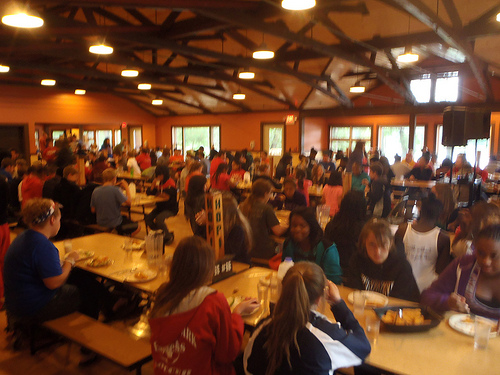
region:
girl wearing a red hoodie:
[142, 228, 249, 373]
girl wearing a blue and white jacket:
[227, 266, 383, 373]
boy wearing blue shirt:
[0, 195, 117, 332]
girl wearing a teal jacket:
[273, 205, 347, 291]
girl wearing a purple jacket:
[406, 223, 498, 316]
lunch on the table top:
[370, 298, 446, 336]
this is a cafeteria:
[2, 112, 494, 373]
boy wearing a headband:
[0, 188, 90, 328]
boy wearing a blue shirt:
[84, 166, 135, 236]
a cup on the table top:
[461, 310, 493, 355]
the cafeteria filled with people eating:
[0, 129, 495, 373]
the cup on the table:
[365, 314, 379, 347]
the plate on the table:
[348, 288, 387, 308]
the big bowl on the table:
[374, 304, 440, 331]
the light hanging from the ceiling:
[249, 34, 274, 61]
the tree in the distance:
[1, 13, 46, 28]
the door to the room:
[260, 120, 285, 169]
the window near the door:
[172, 124, 220, 159]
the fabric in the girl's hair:
[25, 198, 54, 225]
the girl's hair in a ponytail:
[263, 259, 325, 374]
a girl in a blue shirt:
[6, 197, 91, 322]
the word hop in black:
[211, 197, 226, 238]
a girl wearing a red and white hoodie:
[151, 232, 243, 374]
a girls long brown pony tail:
[266, 271, 310, 370]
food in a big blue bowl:
[369, 300, 440, 331]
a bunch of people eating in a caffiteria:
[3, 118, 499, 373]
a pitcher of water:
[142, 230, 164, 263]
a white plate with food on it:
[122, 267, 156, 286]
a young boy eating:
[87, 165, 138, 237]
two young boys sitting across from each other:
[89, 162, 181, 243]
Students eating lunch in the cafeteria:
[68, 138, 473, 351]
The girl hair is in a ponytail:
[266, 260, 314, 351]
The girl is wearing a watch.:
[65, 253, 75, 268]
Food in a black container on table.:
[376, 303, 439, 338]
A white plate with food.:
[451, 296, 490, 334]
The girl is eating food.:
[451, 220, 498, 322]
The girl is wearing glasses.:
[364, 232, 396, 245]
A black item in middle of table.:
[213, 251, 243, 281]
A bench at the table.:
[56, 318, 163, 371]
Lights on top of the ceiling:
[83, 38, 170, 121]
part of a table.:
[99, 238, 112, 250]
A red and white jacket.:
[148, 287, 244, 372]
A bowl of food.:
[375, 301, 440, 333]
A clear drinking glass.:
[473, 320, 490, 351]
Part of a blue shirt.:
[24, 245, 43, 258]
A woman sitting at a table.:
[6, 198, 97, 333]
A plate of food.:
[111, 266, 156, 284]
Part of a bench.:
[83, 315, 128, 362]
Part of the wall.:
[25, 101, 85, 112]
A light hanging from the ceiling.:
[252, 30, 274, 60]